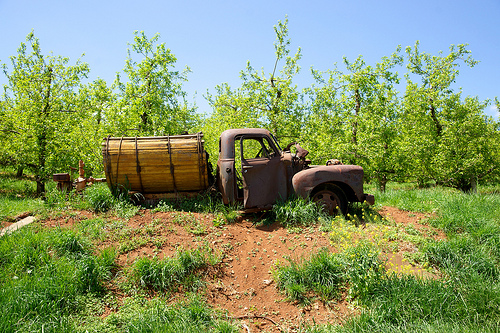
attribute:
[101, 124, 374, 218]
abandoned truck — rusted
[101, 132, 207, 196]
wooden slats — a roll, on back of the truck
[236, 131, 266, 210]
door — ajar, on the truck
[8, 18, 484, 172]
fruit orchard — behind the truck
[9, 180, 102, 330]
green grass — overgrown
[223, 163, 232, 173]
gas cap — on the truck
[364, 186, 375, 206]
bumper — sticks out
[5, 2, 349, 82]
blue sky — sunny, with no clouds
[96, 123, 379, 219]
truck — old, junk, pick up, parked in the field, rusted, broken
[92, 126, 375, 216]
pickup truck — parked in the field, old, junk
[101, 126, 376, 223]
pickup truck — parked in the field, old, junk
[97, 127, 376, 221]
old truck — in an orchard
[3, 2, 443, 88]
blue sky — clear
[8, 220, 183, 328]
green grass — on the ground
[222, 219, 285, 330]
dirt — in the grass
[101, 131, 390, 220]
truck —  old 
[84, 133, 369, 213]
truck — barrel 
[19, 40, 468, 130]
orchard — Trees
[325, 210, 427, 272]
flowers — Yellow 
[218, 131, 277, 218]
door — rusted, old 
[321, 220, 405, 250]
flowers — yellow, small, growing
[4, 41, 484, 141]
trees — leafy, green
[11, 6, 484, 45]
sky — cloudless, blue, clear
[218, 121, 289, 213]
door — open, passenger 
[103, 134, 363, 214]
truck —  old ,  rusted 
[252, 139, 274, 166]
wheel — steering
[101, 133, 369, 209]
truck — inside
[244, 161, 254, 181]
handle — silver, colored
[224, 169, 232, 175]
cap — gas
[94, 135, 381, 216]
car — old, broken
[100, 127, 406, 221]
car — rusty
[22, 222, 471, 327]
grass — green 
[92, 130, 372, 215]
car — handle 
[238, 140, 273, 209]
door — car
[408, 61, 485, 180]
tree —  green